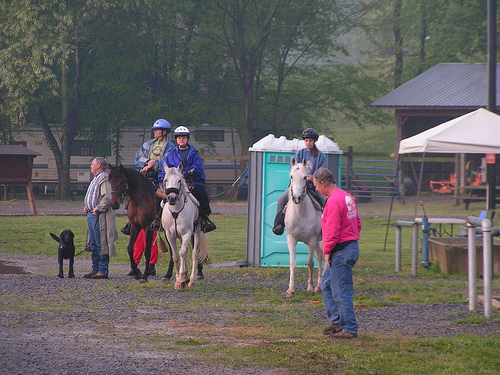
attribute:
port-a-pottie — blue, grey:
[243, 131, 342, 271]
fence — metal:
[343, 142, 402, 194]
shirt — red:
[314, 185, 365, 255]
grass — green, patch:
[355, 340, 492, 374]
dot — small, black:
[289, 152, 306, 162]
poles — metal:
[480, 220, 499, 319]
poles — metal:
[462, 218, 477, 310]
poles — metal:
[409, 222, 420, 282]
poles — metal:
[392, 218, 403, 273]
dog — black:
[40, 222, 97, 284]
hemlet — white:
[169, 122, 188, 134]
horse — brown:
[102, 156, 164, 286]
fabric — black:
[163, 185, 184, 198]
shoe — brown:
[331, 330, 355, 340]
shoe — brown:
[319, 320, 339, 333]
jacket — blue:
[166, 137, 213, 187]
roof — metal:
[372, 43, 483, 128]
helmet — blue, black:
[302, 127, 323, 138]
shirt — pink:
[318, 184, 361, 254]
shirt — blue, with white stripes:
[310, 176, 387, 277]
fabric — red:
[131, 227, 159, 264]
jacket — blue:
[165, 143, 200, 175]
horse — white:
[156, 160, 210, 285]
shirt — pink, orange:
[316, 187, 362, 257]